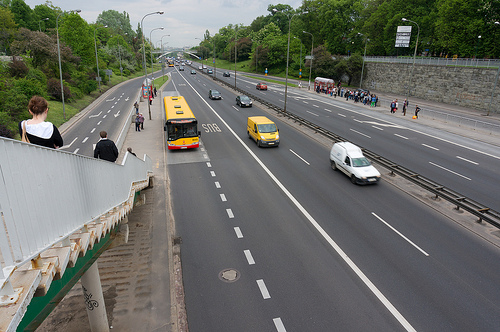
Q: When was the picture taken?
A: Daytime.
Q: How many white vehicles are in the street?
A: One.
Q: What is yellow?
A: A bus.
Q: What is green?
A: Trees.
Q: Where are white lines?
A: On the street.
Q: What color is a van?
A: Yellow.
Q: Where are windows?
A: On vehicles.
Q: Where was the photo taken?
A: On a highway.